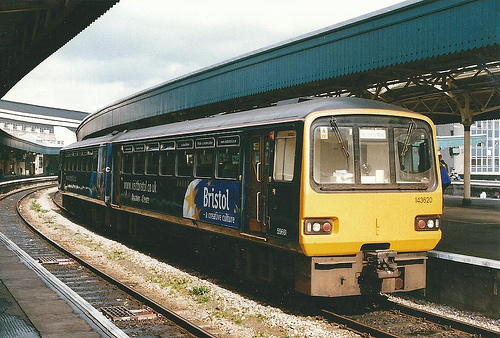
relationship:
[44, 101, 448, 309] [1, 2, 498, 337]
train in railway station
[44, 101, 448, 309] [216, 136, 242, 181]
train has window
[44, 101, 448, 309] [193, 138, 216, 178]
train has window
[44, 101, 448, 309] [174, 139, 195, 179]
train has window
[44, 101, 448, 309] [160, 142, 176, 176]
train has window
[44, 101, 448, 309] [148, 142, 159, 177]
train has window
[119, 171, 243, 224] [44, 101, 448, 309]
advertisement on side of train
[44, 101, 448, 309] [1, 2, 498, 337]
train at railway station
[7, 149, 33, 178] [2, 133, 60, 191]
people standing on platform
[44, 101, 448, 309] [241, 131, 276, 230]
train has door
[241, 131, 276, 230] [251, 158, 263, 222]
door has handles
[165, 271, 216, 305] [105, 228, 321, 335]
grass growing in rocks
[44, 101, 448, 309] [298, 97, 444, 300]
train has front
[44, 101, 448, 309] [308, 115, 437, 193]
train has windshield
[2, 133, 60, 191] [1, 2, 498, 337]
platform in railway station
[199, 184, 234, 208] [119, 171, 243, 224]
words on advertisement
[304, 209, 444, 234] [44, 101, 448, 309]
headlights on train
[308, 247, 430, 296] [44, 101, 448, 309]
coupling on train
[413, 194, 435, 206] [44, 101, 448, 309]
number on train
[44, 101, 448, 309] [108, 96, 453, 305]
train has lead car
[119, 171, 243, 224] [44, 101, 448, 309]
advertisement on train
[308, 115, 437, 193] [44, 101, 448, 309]
windshield on train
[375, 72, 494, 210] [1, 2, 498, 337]
supports for railway station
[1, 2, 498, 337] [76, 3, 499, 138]
railway station has roof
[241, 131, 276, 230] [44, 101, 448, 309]
door on train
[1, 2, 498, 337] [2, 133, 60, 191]
railway station has platform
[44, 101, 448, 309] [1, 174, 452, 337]
train on tracks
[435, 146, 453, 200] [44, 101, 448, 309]
person waiting for train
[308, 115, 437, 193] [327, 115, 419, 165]
windshield has wipers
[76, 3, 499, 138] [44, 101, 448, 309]
roof over train